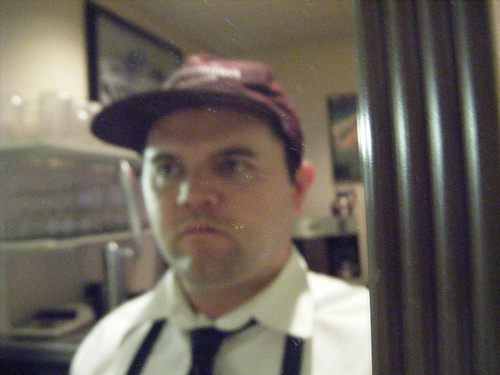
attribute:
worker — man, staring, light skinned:
[66, 49, 372, 374]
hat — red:
[78, 50, 304, 156]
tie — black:
[181, 325, 227, 370]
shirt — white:
[50, 245, 373, 370]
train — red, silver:
[329, 113, 359, 151]